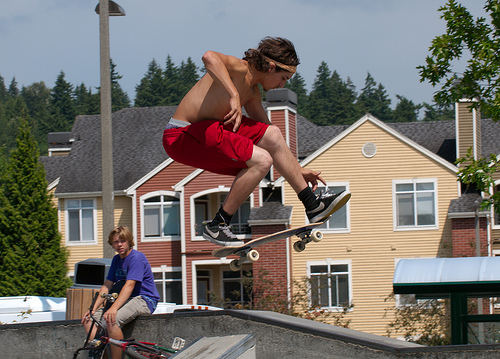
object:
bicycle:
[72, 292, 181, 359]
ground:
[0, 309, 500, 358]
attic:
[277, 114, 466, 184]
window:
[363, 143, 376, 155]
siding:
[321, 167, 437, 174]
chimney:
[454, 94, 481, 170]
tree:
[480, 42, 500, 53]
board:
[212, 214, 333, 271]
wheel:
[293, 241, 306, 252]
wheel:
[310, 230, 323, 243]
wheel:
[229, 259, 242, 271]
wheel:
[246, 250, 259, 263]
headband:
[255, 46, 298, 74]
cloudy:
[352, 22, 415, 66]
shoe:
[304, 190, 351, 223]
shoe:
[202, 221, 244, 245]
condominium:
[36, 88, 500, 346]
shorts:
[89, 295, 153, 330]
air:
[0, 0, 500, 359]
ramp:
[0, 306, 500, 359]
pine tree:
[0, 120, 74, 298]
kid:
[80, 225, 161, 359]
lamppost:
[98, 2, 117, 258]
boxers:
[161, 117, 270, 175]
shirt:
[105, 249, 160, 315]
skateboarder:
[162, 35, 351, 271]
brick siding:
[252, 224, 288, 315]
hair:
[241, 36, 302, 75]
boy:
[72, 226, 179, 359]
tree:
[0, 115, 72, 298]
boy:
[161, 36, 351, 247]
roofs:
[39, 54, 500, 197]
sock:
[297, 185, 319, 211]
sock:
[214, 204, 234, 225]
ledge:
[0, 309, 500, 359]